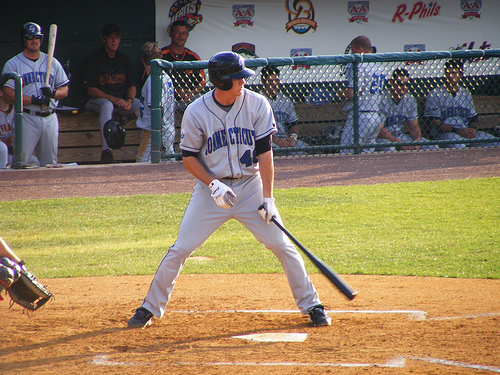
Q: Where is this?
A: This is at the field.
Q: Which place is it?
A: It is a field.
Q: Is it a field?
A: Yes, it is a field.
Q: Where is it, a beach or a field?
A: It is a field.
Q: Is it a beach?
A: No, it is a field.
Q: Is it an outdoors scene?
A: Yes, it is outdoors.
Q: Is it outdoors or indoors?
A: It is outdoors.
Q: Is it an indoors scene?
A: No, it is outdoors.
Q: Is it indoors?
A: No, it is outdoors.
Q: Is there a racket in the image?
A: No, there are no rackets.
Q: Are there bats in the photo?
A: Yes, there is a bat.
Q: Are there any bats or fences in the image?
A: Yes, there is a bat.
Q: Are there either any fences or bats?
A: Yes, there is a bat.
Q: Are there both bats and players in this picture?
A: Yes, there are both a bat and a player.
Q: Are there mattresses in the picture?
A: No, there are no mattresses.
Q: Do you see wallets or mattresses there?
A: No, there are no mattresses or wallets.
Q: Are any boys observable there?
A: No, there are no boys.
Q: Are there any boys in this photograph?
A: No, there are no boys.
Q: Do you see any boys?
A: No, there are no boys.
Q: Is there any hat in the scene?
A: Yes, there is a hat.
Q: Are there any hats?
A: Yes, there is a hat.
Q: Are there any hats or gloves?
A: Yes, there is a hat.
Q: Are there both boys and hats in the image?
A: No, there is a hat but no boys.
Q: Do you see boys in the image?
A: No, there are no boys.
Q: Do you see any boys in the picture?
A: No, there are no boys.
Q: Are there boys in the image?
A: No, there are no boys.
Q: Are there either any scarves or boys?
A: No, there are no boys or scarves.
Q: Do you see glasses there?
A: No, there are no glasses.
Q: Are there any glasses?
A: No, there are no glasses.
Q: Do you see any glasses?
A: No, there are no glasses.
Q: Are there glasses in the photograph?
A: No, there are no glasses.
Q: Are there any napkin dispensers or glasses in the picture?
A: No, there are no glasses or napkin dispensers.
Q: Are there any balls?
A: No, there are no balls.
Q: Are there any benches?
A: Yes, there is a bench.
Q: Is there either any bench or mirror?
A: Yes, there is a bench.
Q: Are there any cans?
A: No, there are no cans.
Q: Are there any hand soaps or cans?
A: No, there are no cans or hand soaps.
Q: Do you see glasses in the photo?
A: No, there are no glasses.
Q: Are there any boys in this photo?
A: No, there are no boys.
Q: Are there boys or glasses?
A: No, there are no boys or glasses.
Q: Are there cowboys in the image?
A: No, there are no cowboys.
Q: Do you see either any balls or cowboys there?
A: No, there are no cowboys or balls.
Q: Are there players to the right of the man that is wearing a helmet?
A: Yes, there is a player to the right of the man.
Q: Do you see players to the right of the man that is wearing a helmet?
A: Yes, there is a player to the right of the man.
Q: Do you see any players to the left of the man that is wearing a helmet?
A: No, the player is to the right of the man.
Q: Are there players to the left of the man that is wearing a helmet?
A: No, the player is to the right of the man.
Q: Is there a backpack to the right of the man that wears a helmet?
A: No, there is a player to the right of the man.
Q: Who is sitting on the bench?
A: The player is sitting on the bench.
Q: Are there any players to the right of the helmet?
A: Yes, there is a player to the right of the helmet.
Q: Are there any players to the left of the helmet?
A: No, the player is to the right of the helmet.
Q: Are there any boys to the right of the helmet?
A: No, there is a player to the right of the helmet.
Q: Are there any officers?
A: No, there are no officers.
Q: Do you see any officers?
A: No, there are no officers.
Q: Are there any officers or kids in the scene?
A: No, there are no officers or kids.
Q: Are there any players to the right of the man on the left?
A: Yes, there is a player to the right of the man.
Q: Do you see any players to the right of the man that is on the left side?
A: Yes, there is a player to the right of the man.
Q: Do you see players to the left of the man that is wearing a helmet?
A: No, the player is to the right of the man.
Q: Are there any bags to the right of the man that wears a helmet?
A: No, there is a player to the right of the man.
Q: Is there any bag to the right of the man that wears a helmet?
A: No, there is a player to the right of the man.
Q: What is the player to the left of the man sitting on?
A: The player is sitting on the bench.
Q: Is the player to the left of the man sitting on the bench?
A: Yes, the player is sitting on the bench.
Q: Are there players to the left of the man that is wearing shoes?
A: Yes, there is a player to the left of the man.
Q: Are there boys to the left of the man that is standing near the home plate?
A: No, there is a player to the left of the man.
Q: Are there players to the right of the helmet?
A: Yes, there is a player to the right of the helmet.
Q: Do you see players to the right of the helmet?
A: Yes, there is a player to the right of the helmet.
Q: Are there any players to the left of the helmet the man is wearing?
A: No, the player is to the right of the helmet.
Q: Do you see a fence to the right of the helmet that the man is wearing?
A: No, there is a player to the right of the helmet.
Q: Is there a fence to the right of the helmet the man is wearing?
A: No, there is a player to the right of the helmet.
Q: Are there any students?
A: No, there are no students.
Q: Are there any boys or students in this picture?
A: No, there are no students or boys.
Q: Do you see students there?
A: No, there are no students.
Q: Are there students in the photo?
A: No, there are no students.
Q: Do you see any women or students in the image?
A: No, there are no students or women.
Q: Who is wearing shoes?
A: The man is wearing shoes.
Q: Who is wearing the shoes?
A: The man is wearing shoes.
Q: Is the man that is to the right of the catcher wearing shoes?
A: Yes, the man is wearing shoes.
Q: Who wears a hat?
A: The man wears a hat.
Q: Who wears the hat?
A: The man wears a hat.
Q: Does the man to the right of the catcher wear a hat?
A: Yes, the man wears a hat.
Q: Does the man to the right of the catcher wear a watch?
A: No, the man wears a hat.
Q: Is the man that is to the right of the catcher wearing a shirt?
A: Yes, the man is wearing a shirt.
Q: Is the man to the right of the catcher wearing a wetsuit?
A: No, the man is wearing a shirt.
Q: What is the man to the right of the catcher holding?
A: The man is holding the bat.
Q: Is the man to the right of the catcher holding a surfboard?
A: No, the man is holding the bat.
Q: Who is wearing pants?
A: The man is wearing pants.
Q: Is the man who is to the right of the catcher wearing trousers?
A: Yes, the man is wearing trousers.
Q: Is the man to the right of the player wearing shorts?
A: No, the man is wearing trousers.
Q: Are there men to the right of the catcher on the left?
A: Yes, there is a man to the right of the catcher.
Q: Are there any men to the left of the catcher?
A: No, the man is to the right of the catcher.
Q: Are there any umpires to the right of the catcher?
A: No, there is a man to the right of the catcher.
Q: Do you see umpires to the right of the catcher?
A: No, there is a man to the right of the catcher.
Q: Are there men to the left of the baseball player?
A: Yes, there is a man to the left of the player.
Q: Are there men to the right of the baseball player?
A: No, the man is to the left of the player.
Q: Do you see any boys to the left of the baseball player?
A: No, there is a man to the left of the player.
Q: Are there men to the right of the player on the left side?
A: Yes, there is a man to the right of the player.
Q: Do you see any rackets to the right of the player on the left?
A: No, there is a man to the right of the player.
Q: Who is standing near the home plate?
A: The man is standing near the home plate.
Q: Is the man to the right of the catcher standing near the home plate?
A: Yes, the man is standing near the home plate.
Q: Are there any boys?
A: No, there are no boys.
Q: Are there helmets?
A: Yes, there is a helmet.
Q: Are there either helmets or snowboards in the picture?
A: Yes, there is a helmet.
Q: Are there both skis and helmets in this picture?
A: No, there is a helmet but no skis.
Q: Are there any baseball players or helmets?
A: Yes, there is a baseball helmet.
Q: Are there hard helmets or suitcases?
A: Yes, there is a hard helmet.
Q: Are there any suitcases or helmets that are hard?
A: Yes, the helmet is hard.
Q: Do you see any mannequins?
A: No, there are no mannequins.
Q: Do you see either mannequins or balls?
A: No, there are no mannequins or balls.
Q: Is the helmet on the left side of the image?
A: Yes, the helmet is on the left of the image.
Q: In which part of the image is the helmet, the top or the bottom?
A: The helmet is in the top of the image.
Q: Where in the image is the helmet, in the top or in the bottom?
A: The helmet is in the top of the image.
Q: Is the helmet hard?
A: Yes, the helmet is hard.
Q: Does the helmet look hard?
A: Yes, the helmet is hard.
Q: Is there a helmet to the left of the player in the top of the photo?
A: Yes, there is a helmet to the left of the player.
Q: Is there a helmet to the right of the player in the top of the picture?
A: No, the helmet is to the left of the player.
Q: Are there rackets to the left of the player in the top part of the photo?
A: No, there is a helmet to the left of the player.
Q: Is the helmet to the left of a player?
A: Yes, the helmet is to the left of a player.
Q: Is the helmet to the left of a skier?
A: No, the helmet is to the left of a player.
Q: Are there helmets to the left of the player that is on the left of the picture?
A: Yes, there is a helmet to the left of the player.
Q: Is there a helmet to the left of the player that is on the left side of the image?
A: Yes, there is a helmet to the left of the player.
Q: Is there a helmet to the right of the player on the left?
A: No, the helmet is to the left of the player.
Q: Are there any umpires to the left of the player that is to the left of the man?
A: No, there is a helmet to the left of the player.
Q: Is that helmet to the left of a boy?
A: No, the helmet is to the left of a player.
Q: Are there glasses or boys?
A: No, there are no glasses or boys.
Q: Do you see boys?
A: No, there are no boys.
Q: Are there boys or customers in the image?
A: No, there are no boys or customers.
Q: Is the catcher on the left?
A: Yes, the catcher is on the left of the image.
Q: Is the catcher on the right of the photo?
A: No, the catcher is on the left of the image.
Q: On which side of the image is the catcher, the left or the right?
A: The catcher is on the left of the image.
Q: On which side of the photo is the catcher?
A: The catcher is on the left of the image.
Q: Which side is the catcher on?
A: The catcher is on the left of the image.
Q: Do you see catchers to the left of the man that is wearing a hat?
A: Yes, there is a catcher to the left of the man.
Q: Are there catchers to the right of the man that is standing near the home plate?
A: No, the catcher is to the left of the man.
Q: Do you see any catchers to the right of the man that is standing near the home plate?
A: No, the catcher is to the left of the man.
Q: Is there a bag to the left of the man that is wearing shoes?
A: No, there is a catcher to the left of the man.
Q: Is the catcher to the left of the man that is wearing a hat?
A: Yes, the catcher is to the left of the man.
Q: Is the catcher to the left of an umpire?
A: No, the catcher is to the left of the man.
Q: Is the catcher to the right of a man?
A: No, the catcher is to the left of a man.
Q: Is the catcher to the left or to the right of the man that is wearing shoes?
A: The catcher is to the left of the man.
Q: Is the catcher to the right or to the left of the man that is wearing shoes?
A: The catcher is to the left of the man.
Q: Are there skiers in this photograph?
A: No, there are no skiers.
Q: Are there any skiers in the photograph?
A: No, there are no skiers.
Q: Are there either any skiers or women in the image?
A: No, there are no skiers or women.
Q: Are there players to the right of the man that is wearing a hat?
A: Yes, there is a player to the right of the man.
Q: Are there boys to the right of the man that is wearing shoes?
A: No, there is a player to the right of the man.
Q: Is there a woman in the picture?
A: No, there are no women.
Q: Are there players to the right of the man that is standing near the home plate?
A: Yes, there is a player to the right of the man.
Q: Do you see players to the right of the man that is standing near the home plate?
A: Yes, there is a player to the right of the man.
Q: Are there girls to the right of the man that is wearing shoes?
A: No, there is a player to the right of the man.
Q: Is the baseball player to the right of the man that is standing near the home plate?
A: Yes, the player is to the right of the man.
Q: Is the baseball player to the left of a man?
A: No, the player is to the right of a man.